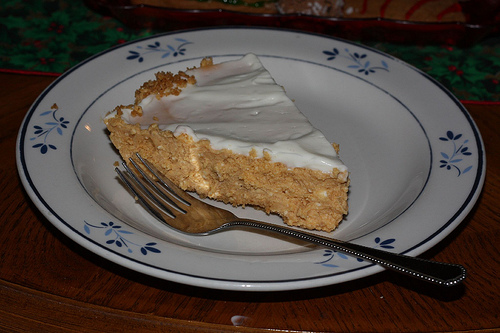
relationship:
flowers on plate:
[35, 29, 472, 270] [269, 32, 498, 247]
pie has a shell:
[96, 51, 350, 237] [118, 72, 208, 108]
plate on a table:
[15, 40, 489, 285] [0, 68, 499, 333]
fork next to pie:
[88, 81, 473, 320] [96, 51, 350, 237]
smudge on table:
[221, 308, 246, 327] [3, 1, 498, 329]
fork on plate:
[112, 157, 471, 292] [17, 25, 484, 296]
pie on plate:
[96, 51, 350, 237] [15, 26, 490, 292]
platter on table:
[122, 0, 479, 46] [3, 1, 498, 329]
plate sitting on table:
[15, 26, 490, 292] [3, 57, 498, 330]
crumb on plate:
[43, 96, 60, 108] [17, 25, 484, 296]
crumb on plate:
[111, 155, 127, 177] [17, 25, 484, 296]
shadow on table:
[380, 276, 467, 303] [348, 294, 470, 329]